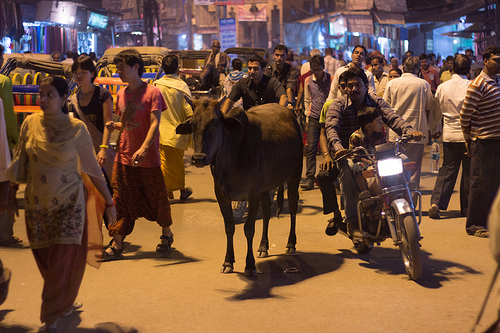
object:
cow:
[173, 91, 305, 280]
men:
[313, 75, 423, 238]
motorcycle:
[324, 139, 429, 283]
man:
[91, 49, 176, 257]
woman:
[63, 54, 114, 231]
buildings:
[103, 2, 408, 69]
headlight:
[372, 158, 403, 178]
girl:
[12, 76, 117, 332]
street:
[1, 151, 499, 332]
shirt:
[114, 83, 169, 167]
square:
[0, 65, 499, 330]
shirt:
[434, 74, 472, 142]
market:
[0, 1, 499, 332]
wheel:
[395, 216, 423, 281]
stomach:
[233, 176, 294, 202]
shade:
[221, 249, 343, 300]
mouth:
[188, 154, 206, 168]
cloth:
[83, 204, 128, 253]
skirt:
[6, 112, 106, 249]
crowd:
[294, 53, 335, 189]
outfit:
[13, 114, 112, 331]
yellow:
[163, 84, 188, 151]